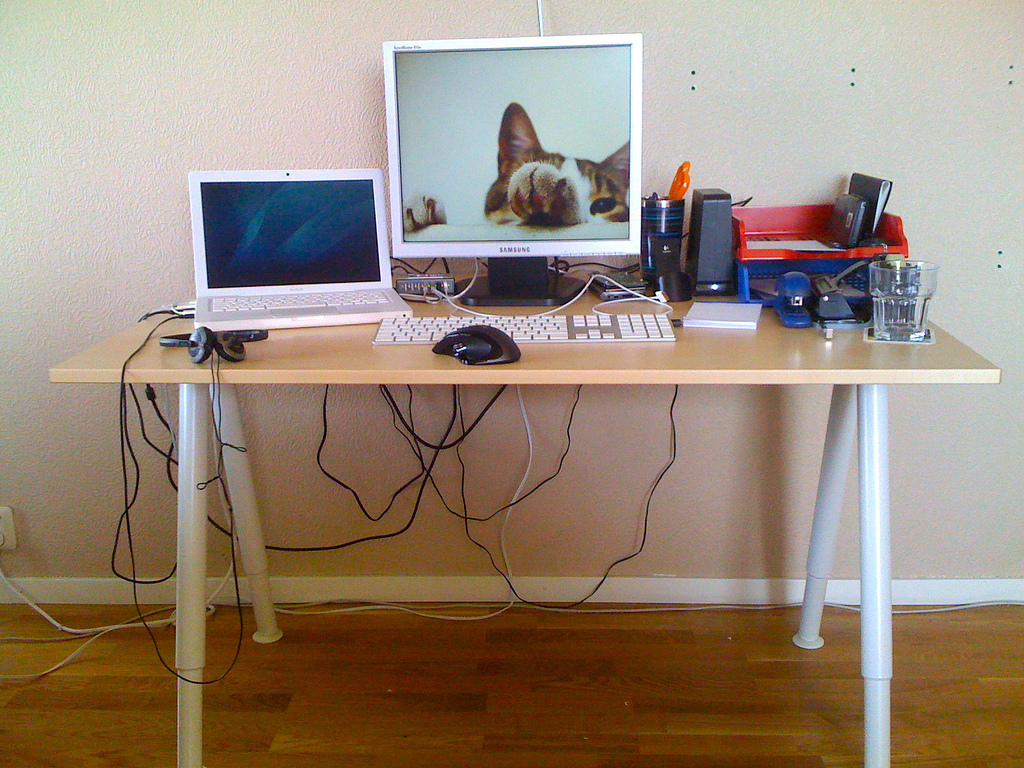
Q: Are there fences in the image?
A: No, there are no fences.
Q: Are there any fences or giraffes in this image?
A: No, there are no fences or giraffes.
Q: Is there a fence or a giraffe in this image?
A: No, there are no fences or giraffes.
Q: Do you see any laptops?
A: Yes, there is a laptop.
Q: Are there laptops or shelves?
A: Yes, there is a laptop.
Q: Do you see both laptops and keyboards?
A: Yes, there are both a laptop and a keyboard.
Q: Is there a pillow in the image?
A: No, there are no pillows.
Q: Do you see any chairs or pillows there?
A: No, there are no pillows or chairs.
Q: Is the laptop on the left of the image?
A: Yes, the laptop is on the left of the image.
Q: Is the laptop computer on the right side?
A: No, the laptop computer is on the left of the image.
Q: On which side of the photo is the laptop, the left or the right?
A: The laptop is on the left of the image.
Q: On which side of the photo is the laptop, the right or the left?
A: The laptop is on the left of the image.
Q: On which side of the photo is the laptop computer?
A: The laptop computer is on the left of the image.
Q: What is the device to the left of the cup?
A: The device is a laptop.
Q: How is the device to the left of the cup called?
A: The device is a laptop.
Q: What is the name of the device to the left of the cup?
A: The device is a laptop.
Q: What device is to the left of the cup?
A: The device is a laptop.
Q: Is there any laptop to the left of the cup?
A: Yes, there is a laptop to the left of the cup.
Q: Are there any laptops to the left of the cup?
A: Yes, there is a laptop to the left of the cup.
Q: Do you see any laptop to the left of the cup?
A: Yes, there is a laptop to the left of the cup.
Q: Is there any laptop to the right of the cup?
A: No, the laptop is to the left of the cup.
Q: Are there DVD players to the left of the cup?
A: No, there is a laptop to the left of the cup.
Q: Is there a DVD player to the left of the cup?
A: No, there is a laptop to the left of the cup.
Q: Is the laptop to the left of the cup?
A: Yes, the laptop is to the left of the cup.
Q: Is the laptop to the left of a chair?
A: No, the laptop is to the left of the cup.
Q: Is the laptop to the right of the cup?
A: No, the laptop is to the left of the cup.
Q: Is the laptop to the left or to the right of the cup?
A: The laptop is to the left of the cup.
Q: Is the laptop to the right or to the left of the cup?
A: The laptop is to the left of the cup.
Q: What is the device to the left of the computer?
A: The device is a laptop.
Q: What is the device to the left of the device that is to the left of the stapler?
A: The device is a laptop.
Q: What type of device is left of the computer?
A: The device is a laptop.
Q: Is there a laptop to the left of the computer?
A: Yes, there is a laptop to the left of the computer.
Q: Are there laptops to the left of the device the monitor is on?
A: Yes, there is a laptop to the left of the computer.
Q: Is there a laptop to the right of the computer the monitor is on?
A: No, the laptop is to the left of the computer.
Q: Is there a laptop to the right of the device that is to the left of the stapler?
A: No, the laptop is to the left of the computer.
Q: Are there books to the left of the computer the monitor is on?
A: No, there is a laptop to the left of the computer.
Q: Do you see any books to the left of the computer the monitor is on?
A: No, there is a laptop to the left of the computer.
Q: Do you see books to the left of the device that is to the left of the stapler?
A: No, there is a laptop to the left of the computer.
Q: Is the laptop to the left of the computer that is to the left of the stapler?
A: Yes, the laptop is to the left of the computer.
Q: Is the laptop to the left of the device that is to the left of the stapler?
A: Yes, the laptop is to the left of the computer.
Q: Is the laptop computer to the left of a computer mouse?
A: No, the laptop computer is to the left of the computer.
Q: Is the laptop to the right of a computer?
A: No, the laptop is to the left of a computer.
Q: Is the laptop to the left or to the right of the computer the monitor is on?
A: The laptop is to the left of the computer.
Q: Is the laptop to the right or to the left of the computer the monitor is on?
A: The laptop is to the left of the computer.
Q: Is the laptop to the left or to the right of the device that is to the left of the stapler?
A: The laptop is to the left of the computer.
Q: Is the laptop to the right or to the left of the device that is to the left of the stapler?
A: The laptop is to the left of the computer.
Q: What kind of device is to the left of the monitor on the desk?
A: The device is a laptop.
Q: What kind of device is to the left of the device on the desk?
A: The device is a laptop.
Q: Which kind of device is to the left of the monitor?
A: The device is a laptop.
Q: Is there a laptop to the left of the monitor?
A: Yes, there is a laptop to the left of the monitor.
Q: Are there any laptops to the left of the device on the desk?
A: Yes, there is a laptop to the left of the monitor.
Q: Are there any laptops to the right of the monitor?
A: No, the laptop is to the left of the monitor.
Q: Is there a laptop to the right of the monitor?
A: No, the laptop is to the left of the monitor.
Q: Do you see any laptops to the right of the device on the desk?
A: No, the laptop is to the left of the monitor.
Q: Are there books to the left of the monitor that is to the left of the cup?
A: No, there is a laptop to the left of the monitor.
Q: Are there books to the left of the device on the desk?
A: No, there is a laptop to the left of the monitor.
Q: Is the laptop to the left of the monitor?
A: Yes, the laptop is to the left of the monitor.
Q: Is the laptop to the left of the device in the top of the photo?
A: Yes, the laptop is to the left of the monitor.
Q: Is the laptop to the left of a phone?
A: No, the laptop is to the left of the monitor.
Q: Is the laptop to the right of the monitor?
A: No, the laptop is to the left of the monitor.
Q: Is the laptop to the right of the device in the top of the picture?
A: No, the laptop is to the left of the monitor.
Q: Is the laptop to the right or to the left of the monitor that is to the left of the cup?
A: The laptop is to the left of the monitor.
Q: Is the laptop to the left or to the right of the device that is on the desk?
A: The laptop is to the left of the monitor.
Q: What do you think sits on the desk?
A: The laptop computer sits on the desk.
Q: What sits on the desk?
A: The laptop computer sits on the desk.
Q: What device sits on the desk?
A: The device is a laptop.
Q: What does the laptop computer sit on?
A: The laptop computer sits on the desk.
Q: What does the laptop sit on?
A: The laptop computer sits on the desk.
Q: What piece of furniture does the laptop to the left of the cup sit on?
A: The laptop sits on the desk.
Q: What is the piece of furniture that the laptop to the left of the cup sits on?
A: The piece of furniture is a desk.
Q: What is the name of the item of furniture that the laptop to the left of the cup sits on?
A: The piece of furniture is a desk.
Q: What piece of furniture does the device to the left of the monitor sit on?
A: The laptop sits on the desk.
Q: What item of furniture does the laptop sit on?
A: The laptop sits on the desk.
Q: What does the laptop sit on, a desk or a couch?
A: The laptop sits on a desk.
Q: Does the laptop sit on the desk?
A: Yes, the laptop sits on the desk.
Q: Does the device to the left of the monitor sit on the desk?
A: Yes, the laptop sits on the desk.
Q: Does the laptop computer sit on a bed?
A: No, the laptop computer sits on the desk.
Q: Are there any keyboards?
A: Yes, there is a keyboard.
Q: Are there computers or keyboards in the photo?
A: Yes, there is a keyboard.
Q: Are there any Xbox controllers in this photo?
A: No, there are no Xbox controllers.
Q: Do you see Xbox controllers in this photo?
A: No, there are no Xbox controllers.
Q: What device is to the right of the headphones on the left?
A: The device is a keyboard.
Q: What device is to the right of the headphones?
A: The device is a keyboard.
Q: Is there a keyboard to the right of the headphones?
A: Yes, there is a keyboard to the right of the headphones.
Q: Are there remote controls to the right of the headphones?
A: No, there is a keyboard to the right of the headphones.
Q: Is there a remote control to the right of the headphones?
A: No, there is a keyboard to the right of the headphones.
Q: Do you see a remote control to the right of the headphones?
A: No, there is a keyboard to the right of the headphones.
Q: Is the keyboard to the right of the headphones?
A: Yes, the keyboard is to the right of the headphones.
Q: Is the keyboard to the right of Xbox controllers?
A: No, the keyboard is to the right of the headphones.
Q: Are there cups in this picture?
A: Yes, there is a cup.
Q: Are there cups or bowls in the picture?
A: Yes, there is a cup.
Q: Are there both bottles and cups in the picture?
A: No, there is a cup but no bottles.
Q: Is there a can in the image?
A: No, there are no cans.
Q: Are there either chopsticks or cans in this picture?
A: No, there are no cans or chopsticks.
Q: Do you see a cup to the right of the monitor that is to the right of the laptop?
A: Yes, there is a cup to the right of the monitor.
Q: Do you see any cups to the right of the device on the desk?
A: Yes, there is a cup to the right of the monitor.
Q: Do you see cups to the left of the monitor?
A: No, the cup is to the right of the monitor.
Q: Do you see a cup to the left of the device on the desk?
A: No, the cup is to the right of the monitor.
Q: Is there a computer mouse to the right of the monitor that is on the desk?
A: No, there is a cup to the right of the monitor.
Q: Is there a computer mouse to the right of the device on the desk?
A: No, there is a cup to the right of the monitor.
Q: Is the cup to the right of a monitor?
A: Yes, the cup is to the right of a monitor.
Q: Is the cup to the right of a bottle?
A: No, the cup is to the right of a monitor.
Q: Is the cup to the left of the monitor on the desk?
A: No, the cup is to the right of the monitor.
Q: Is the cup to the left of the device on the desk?
A: No, the cup is to the right of the monitor.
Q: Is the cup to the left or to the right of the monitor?
A: The cup is to the right of the monitor.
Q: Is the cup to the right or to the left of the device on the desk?
A: The cup is to the right of the monitor.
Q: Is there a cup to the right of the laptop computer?
A: Yes, there is a cup to the right of the laptop computer.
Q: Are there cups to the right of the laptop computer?
A: Yes, there is a cup to the right of the laptop computer.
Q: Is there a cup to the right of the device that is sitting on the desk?
A: Yes, there is a cup to the right of the laptop computer.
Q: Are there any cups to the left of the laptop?
A: No, the cup is to the right of the laptop.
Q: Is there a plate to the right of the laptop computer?
A: No, there is a cup to the right of the laptop computer.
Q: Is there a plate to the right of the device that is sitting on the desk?
A: No, there is a cup to the right of the laptop computer.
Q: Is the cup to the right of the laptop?
A: Yes, the cup is to the right of the laptop.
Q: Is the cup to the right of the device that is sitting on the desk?
A: Yes, the cup is to the right of the laptop.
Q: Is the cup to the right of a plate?
A: No, the cup is to the right of the laptop.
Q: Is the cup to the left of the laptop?
A: No, the cup is to the right of the laptop.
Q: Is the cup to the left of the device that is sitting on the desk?
A: No, the cup is to the right of the laptop.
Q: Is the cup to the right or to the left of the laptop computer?
A: The cup is to the right of the laptop computer.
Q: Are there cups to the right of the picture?
A: Yes, there is a cup to the right of the picture.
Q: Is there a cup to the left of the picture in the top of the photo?
A: No, the cup is to the right of the picture.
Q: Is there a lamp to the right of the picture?
A: No, there is a cup to the right of the picture.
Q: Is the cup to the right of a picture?
A: Yes, the cup is to the right of a picture.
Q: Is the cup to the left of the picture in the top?
A: No, the cup is to the right of the picture.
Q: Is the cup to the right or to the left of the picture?
A: The cup is to the right of the picture.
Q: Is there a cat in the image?
A: Yes, there is a cat.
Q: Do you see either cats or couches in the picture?
A: Yes, there is a cat.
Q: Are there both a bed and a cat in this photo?
A: No, there is a cat but no beds.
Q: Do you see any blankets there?
A: No, there are no blankets.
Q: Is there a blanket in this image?
A: No, there are no blankets.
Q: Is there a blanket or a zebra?
A: No, there are no blankets or zebras.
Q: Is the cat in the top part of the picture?
A: Yes, the cat is in the top of the image.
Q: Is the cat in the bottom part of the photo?
A: No, the cat is in the top of the image.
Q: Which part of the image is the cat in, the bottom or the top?
A: The cat is in the top of the image.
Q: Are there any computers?
A: Yes, there is a computer.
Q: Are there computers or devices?
A: Yes, there is a computer.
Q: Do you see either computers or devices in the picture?
A: Yes, there is a computer.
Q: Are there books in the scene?
A: No, there are no books.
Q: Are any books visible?
A: No, there are no books.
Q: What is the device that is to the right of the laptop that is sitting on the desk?
A: The device is a computer.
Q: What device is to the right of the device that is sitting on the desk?
A: The device is a computer.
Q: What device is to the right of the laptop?
A: The device is a computer.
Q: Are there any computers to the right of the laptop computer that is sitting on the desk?
A: Yes, there is a computer to the right of the laptop.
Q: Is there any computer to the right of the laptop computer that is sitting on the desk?
A: Yes, there is a computer to the right of the laptop.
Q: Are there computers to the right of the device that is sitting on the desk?
A: Yes, there is a computer to the right of the laptop.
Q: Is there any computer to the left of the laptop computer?
A: No, the computer is to the right of the laptop computer.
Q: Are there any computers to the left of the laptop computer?
A: No, the computer is to the right of the laptop computer.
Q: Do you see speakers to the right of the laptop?
A: No, there is a computer to the right of the laptop.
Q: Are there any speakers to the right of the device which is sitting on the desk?
A: No, there is a computer to the right of the laptop.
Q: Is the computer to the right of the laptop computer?
A: Yes, the computer is to the right of the laptop computer.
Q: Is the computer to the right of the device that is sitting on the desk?
A: Yes, the computer is to the right of the laptop computer.